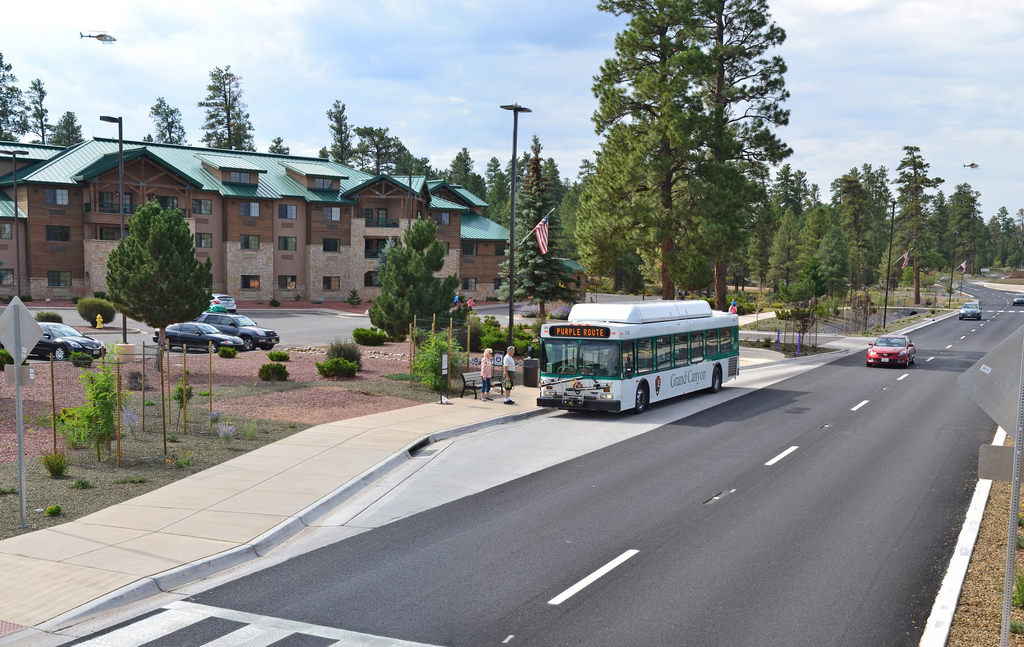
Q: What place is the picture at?
A: It is at the road.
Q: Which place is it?
A: It is a road.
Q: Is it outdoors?
A: Yes, it is outdoors.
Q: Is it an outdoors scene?
A: Yes, it is outdoors.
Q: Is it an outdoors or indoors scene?
A: It is outdoors.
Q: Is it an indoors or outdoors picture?
A: It is outdoors.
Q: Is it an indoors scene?
A: No, it is outdoors.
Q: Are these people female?
A: No, they are both male and female.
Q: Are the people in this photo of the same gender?
A: No, they are both male and female.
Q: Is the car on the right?
A: Yes, the car is on the right of the image.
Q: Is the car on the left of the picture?
A: No, the car is on the right of the image.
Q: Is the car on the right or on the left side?
A: The car is on the right of the image.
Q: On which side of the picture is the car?
A: The car is on the right of the image.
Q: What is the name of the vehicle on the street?
A: The vehicle is a car.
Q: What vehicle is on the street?
A: The vehicle is a car.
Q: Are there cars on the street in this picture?
A: Yes, there is a car on the street.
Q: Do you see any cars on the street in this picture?
A: Yes, there is a car on the street.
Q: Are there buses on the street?
A: No, there is a car on the street.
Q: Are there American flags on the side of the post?
A: Yes, there is an American flag on the side of the post.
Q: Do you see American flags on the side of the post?
A: Yes, there is an American flag on the side of the post.